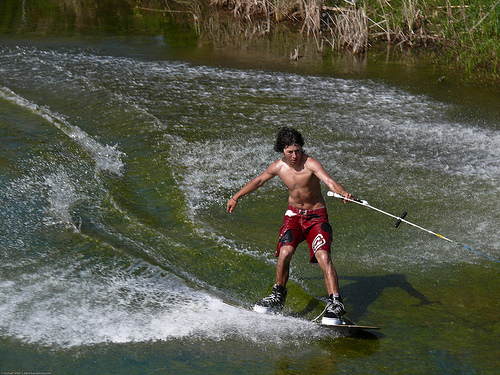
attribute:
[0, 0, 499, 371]
water — green, white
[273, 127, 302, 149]
hair — black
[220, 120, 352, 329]
man — shirtless, holding, skiing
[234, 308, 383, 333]
board — water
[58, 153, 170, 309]
water — white, green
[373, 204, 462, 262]
rope — attached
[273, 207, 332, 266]
shorts — red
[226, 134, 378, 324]
man — water skiing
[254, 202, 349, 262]
man — black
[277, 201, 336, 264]
shorts — red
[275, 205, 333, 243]
shorts — red